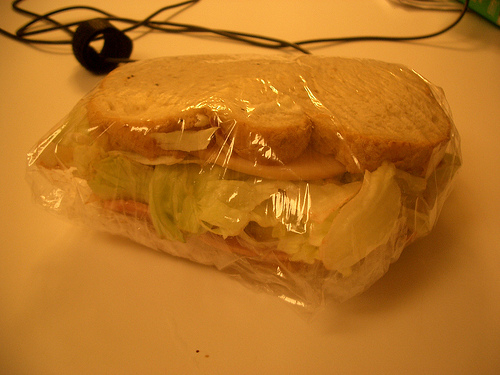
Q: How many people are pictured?
A: 0.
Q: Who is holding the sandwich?
A: Nobody.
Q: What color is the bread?
A: White.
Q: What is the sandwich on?
A: Table.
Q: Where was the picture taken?
A: House.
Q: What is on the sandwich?
A: Lettuce.